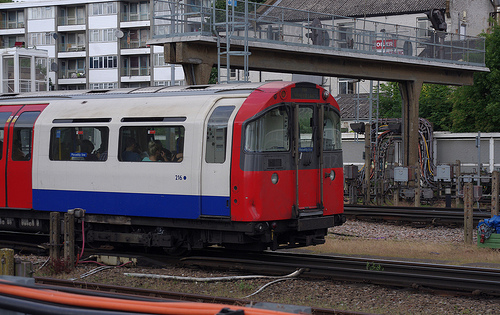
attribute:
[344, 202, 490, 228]
train tracks — set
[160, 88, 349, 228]
train — red, white, blue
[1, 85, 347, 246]
train — passenger train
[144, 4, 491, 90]
walkway — overhead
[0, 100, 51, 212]
door — red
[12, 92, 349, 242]
train — white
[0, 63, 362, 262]
train — red, white, blue